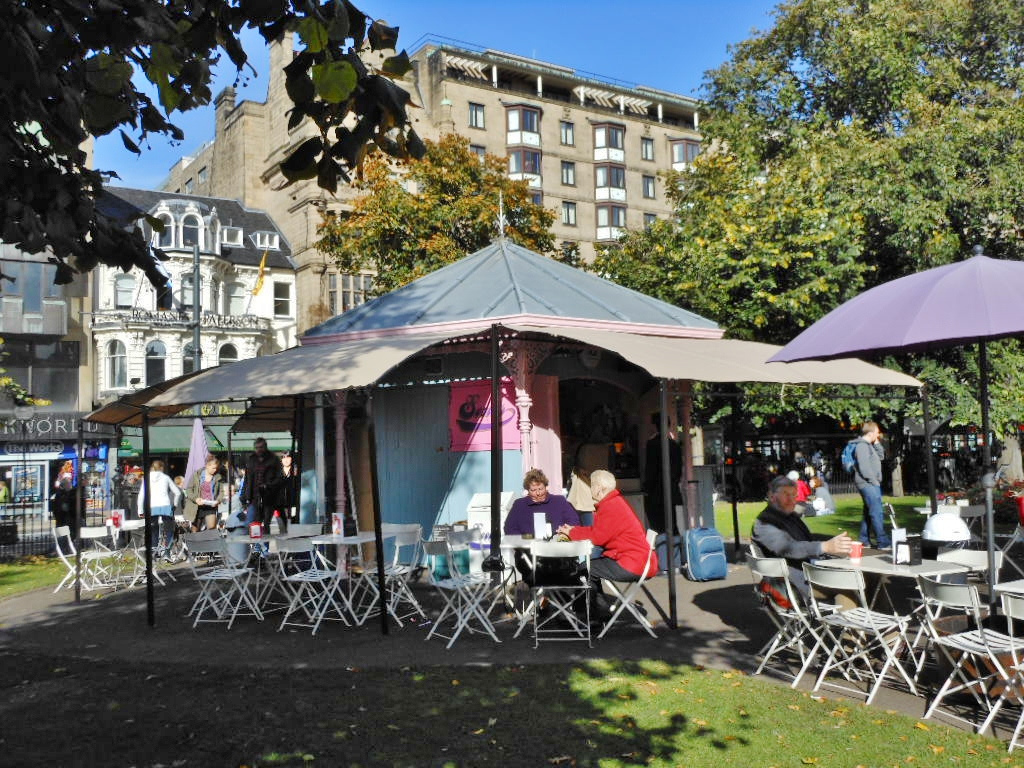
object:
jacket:
[504, 493, 581, 536]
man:
[750, 476, 925, 658]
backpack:
[680, 527, 728, 582]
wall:
[526, 357, 679, 530]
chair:
[530, 539, 595, 650]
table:
[471, 535, 595, 638]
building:
[79, 190, 928, 587]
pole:
[141, 407, 155, 627]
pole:
[365, 389, 390, 636]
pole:
[658, 379, 678, 630]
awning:
[140, 326, 494, 408]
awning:
[497, 325, 922, 387]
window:
[146, 340, 167, 386]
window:
[183, 342, 194, 374]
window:
[219, 343, 238, 365]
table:
[311, 531, 396, 636]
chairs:
[276, 538, 352, 636]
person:
[504, 468, 582, 619]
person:
[556, 469, 659, 623]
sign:
[448, 376, 521, 452]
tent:
[182, 523, 428, 636]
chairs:
[51, 499, 1023, 754]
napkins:
[892, 528, 908, 566]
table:
[814, 553, 987, 693]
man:
[842, 420, 893, 552]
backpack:
[841, 439, 863, 473]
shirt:
[504, 494, 581, 535]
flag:
[251, 248, 269, 295]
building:
[93, 186, 296, 520]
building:
[158, 24, 713, 331]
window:
[591, 122, 626, 161]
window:
[274, 281, 290, 315]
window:
[507, 151, 522, 174]